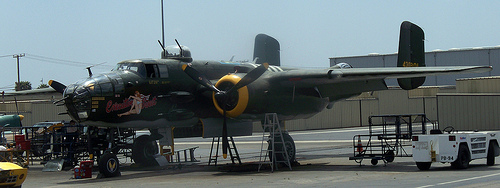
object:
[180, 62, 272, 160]
propeller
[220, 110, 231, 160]
blades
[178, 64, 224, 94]
blades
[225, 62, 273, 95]
blades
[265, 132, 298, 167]
wheel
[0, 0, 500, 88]
blue sky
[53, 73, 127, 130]
nose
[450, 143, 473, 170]
wheel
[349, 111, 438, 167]
cargo carrier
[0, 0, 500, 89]
clouds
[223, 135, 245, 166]
ladder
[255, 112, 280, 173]
ladder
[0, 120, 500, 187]
airport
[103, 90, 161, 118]
logo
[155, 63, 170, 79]
window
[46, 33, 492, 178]
airplane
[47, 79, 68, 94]
propeller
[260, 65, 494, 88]
wing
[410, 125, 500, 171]
cargo carrier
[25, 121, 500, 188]
runway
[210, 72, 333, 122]
plane engine